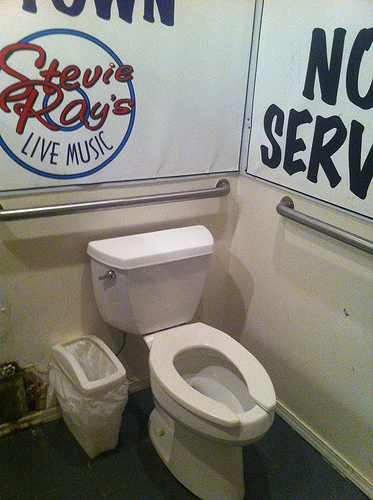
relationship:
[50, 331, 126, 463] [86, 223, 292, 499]
trash can near toilet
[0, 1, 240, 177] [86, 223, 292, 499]
sign behind toilet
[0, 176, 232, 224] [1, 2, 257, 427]
metal bar on wall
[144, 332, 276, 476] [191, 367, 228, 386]
bowl filled with water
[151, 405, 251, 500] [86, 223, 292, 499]
base of toilet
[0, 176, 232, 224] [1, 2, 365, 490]
towel rack in bathroom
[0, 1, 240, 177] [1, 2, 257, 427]
advertisement on wall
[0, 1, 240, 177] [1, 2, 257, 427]
sign on wall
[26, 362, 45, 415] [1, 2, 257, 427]
hole in wall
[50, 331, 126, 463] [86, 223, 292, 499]
garbage can next to toilet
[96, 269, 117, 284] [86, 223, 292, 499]
handle on toilet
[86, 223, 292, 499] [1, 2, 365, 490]
toilet in bathroom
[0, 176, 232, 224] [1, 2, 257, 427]
railing on wall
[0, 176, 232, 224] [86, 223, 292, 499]
railing behind toilet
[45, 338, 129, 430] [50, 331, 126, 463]
bag in garbage can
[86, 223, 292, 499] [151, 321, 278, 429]
toilet has no lid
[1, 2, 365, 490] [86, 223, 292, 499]
bathroom has a toilet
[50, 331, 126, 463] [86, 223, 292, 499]
trash can next to toilet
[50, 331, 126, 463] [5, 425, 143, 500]
trash can on floor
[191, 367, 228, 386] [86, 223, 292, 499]
water in toilet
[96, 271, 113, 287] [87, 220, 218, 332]
handle on tank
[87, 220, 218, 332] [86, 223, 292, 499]
tank on toilet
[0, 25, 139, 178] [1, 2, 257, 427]
logo on wall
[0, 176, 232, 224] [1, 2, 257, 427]
handle on wall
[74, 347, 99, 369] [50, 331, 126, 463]
bag in trash can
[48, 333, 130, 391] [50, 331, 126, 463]
lid on top of trash can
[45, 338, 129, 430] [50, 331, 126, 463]
bag in trash can